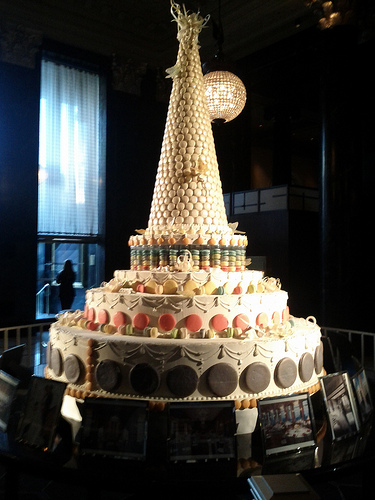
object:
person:
[56, 256, 79, 312]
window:
[36, 52, 108, 314]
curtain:
[30, 37, 107, 297]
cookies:
[207, 358, 239, 398]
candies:
[211, 309, 230, 334]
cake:
[30, 2, 332, 443]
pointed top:
[123, 0, 248, 234]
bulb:
[199, 67, 249, 126]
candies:
[163, 278, 179, 294]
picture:
[257, 389, 320, 461]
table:
[0, 318, 373, 500]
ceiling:
[4, 0, 364, 42]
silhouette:
[55, 256, 79, 309]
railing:
[1, 311, 49, 355]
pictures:
[162, 398, 239, 471]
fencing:
[2, 316, 372, 440]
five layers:
[42, 225, 327, 402]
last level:
[126, 227, 250, 270]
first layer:
[43, 325, 326, 405]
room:
[0, 0, 374, 500]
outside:
[41, 218, 97, 311]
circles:
[132, 310, 149, 330]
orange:
[185, 312, 204, 333]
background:
[0, 34, 374, 305]